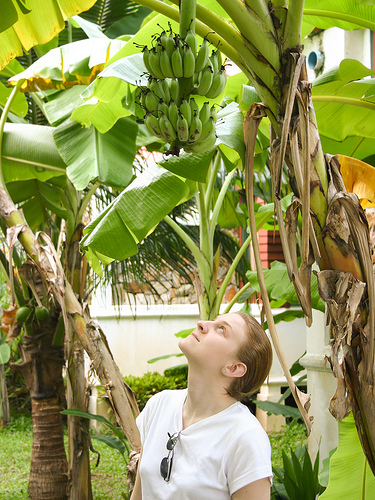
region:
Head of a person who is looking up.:
[176, 309, 274, 399]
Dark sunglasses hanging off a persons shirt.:
[159, 428, 181, 482]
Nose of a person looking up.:
[196, 320, 214, 333]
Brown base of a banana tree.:
[25, 383, 73, 498]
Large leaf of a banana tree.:
[82, 154, 189, 274]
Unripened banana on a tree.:
[177, 113, 188, 144]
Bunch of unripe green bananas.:
[137, 21, 226, 154]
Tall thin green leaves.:
[272, 447, 323, 498]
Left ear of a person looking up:
[219, 361, 247, 379]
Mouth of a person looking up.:
[189, 332, 200, 343]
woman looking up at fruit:
[124, 306, 294, 497]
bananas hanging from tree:
[129, 8, 254, 172]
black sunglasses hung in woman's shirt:
[144, 417, 195, 492]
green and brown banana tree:
[13, 13, 359, 266]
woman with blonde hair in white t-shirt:
[124, 292, 295, 495]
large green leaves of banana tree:
[84, 138, 231, 283]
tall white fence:
[122, 289, 326, 373]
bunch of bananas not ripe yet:
[117, 9, 270, 177]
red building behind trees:
[227, 164, 310, 303]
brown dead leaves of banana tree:
[318, 192, 374, 301]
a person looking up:
[118, 305, 292, 496]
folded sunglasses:
[150, 421, 190, 483]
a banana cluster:
[124, 0, 233, 170]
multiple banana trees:
[0, 0, 370, 495]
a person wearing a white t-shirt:
[117, 303, 284, 496]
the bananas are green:
[128, 1, 243, 167]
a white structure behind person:
[57, 23, 373, 488]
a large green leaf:
[65, 135, 240, 275]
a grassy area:
[0, 402, 310, 497]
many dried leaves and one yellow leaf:
[236, 43, 373, 477]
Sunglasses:
[158, 431, 179, 480]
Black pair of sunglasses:
[157, 429, 181, 482]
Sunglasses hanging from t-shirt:
[158, 431, 182, 482]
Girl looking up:
[128, 311, 271, 499]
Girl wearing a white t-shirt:
[128, 311, 271, 499]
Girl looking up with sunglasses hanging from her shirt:
[128, 311, 273, 498]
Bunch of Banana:
[139, 22, 227, 144]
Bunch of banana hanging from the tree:
[137, 24, 226, 155]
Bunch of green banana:
[133, 24, 227, 156]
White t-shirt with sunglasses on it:
[134, 388, 273, 498]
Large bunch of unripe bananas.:
[135, 16, 228, 153]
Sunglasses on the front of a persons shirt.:
[160, 428, 181, 481]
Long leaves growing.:
[279, 443, 325, 498]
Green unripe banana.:
[159, 43, 172, 78]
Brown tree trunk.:
[23, 370, 70, 498]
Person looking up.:
[128, 311, 272, 498]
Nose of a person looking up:
[196, 318, 214, 331]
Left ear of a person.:
[221, 360, 251, 381]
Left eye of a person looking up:
[212, 323, 229, 335]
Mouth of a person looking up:
[188, 333, 200, 344]